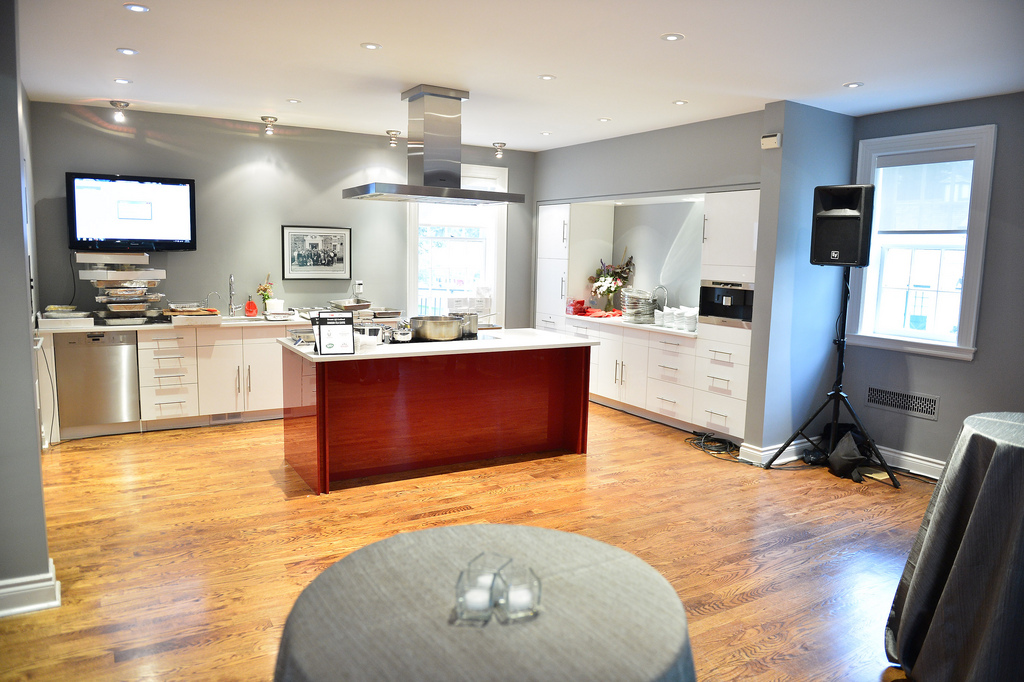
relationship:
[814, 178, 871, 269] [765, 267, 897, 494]
speaker on stand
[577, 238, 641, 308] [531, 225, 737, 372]
flowers on counter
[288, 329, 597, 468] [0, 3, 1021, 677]
counter in middle of kitchen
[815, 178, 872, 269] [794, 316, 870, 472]
speaker on stand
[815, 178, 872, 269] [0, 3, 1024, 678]
speaker in room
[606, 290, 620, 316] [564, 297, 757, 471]
vase on counter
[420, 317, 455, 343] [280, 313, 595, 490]
pot on top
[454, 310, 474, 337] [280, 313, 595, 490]
pot on top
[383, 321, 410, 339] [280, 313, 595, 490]
pot on top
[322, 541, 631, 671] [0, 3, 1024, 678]
table in room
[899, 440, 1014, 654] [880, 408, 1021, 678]
tablecloth on table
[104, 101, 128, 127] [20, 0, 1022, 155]
light fixture in ceiling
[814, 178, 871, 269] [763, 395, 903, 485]
speaker on stand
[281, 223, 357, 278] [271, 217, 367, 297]
frame in frame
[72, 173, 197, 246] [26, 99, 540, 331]
screen on wall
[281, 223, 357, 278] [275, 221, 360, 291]
frame in a frame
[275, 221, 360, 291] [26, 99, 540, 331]
frame on a wall